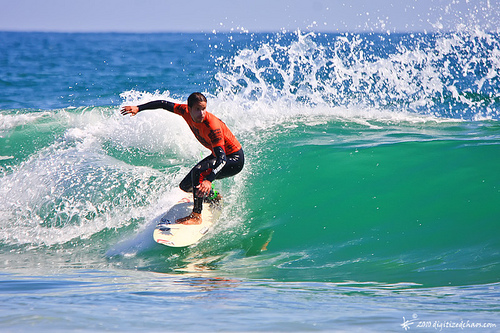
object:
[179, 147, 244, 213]
pants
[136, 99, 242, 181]
shirt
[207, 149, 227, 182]
sleeve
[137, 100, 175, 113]
sleeve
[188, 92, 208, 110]
brown hair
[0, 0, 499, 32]
sky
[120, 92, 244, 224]
person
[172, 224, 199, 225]
left foot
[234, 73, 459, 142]
wall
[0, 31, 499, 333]
water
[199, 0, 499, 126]
ocean spray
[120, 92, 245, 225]
surfer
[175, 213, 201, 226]
barefoot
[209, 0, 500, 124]
foam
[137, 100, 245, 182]
wetsuit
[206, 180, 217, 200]
strap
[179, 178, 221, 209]
leg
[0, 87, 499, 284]
wave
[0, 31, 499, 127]
ocean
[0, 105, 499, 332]
ocean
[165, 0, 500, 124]
spray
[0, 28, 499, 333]
sea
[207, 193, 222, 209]
foot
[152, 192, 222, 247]
surfboard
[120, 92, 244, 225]
man